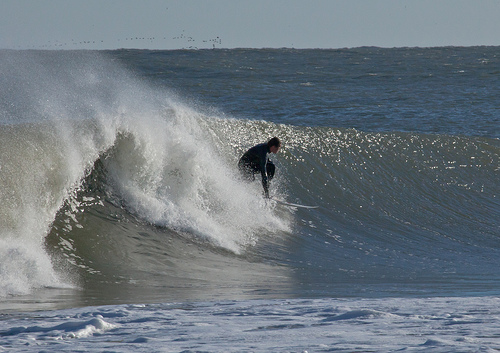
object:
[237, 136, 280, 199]
man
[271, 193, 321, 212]
surfboard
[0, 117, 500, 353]
waves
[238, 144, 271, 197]
surfing outfit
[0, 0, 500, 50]
blue skies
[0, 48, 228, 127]
splash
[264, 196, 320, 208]
board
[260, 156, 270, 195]
arm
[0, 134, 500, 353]
ripples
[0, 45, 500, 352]
water